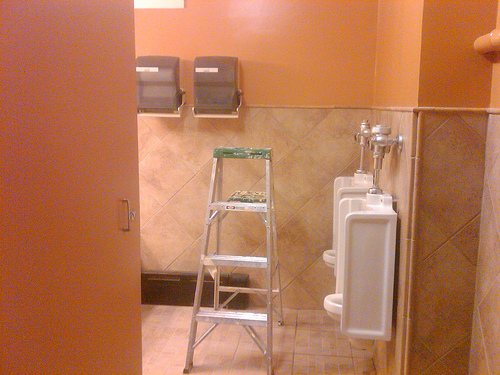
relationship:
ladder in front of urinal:
[183, 147, 284, 374] [323, 124, 404, 343]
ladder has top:
[183, 147, 284, 374] [214, 147, 273, 160]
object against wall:
[141, 269, 250, 311] [134, 0, 500, 375]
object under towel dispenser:
[141, 269, 250, 311] [192, 55, 242, 120]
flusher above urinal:
[354, 120, 372, 146] [322, 119, 378, 278]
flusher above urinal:
[369, 123, 397, 156] [323, 123, 404, 343]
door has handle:
[0, 0, 142, 374] [122, 199, 131, 232]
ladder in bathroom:
[183, 147, 284, 374] [0, 0, 499, 374]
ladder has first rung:
[183, 147, 284, 374] [195, 308, 268, 331]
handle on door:
[122, 199, 131, 232] [0, 0, 142, 374]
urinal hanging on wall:
[323, 124, 404, 343] [134, 0, 500, 375]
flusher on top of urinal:
[354, 120, 372, 146] [322, 119, 378, 278]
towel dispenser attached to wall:
[192, 55, 242, 120] [134, 0, 500, 375]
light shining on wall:
[228, 1, 285, 34] [134, 0, 500, 375]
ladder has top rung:
[183, 147, 284, 374] [209, 195, 268, 215]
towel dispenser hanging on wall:
[192, 55, 242, 120] [134, 0, 500, 375]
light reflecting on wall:
[228, 1, 285, 34] [134, 0, 500, 375]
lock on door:
[129, 209, 138, 221] [0, 0, 142, 374]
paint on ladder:
[233, 187, 268, 201] [183, 147, 284, 374]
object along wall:
[141, 269, 250, 311] [134, 0, 500, 375]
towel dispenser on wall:
[135, 55, 186, 119] [134, 0, 500, 375]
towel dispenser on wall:
[193, 55, 243, 118] [134, 0, 500, 375]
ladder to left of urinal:
[183, 147, 284, 374] [323, 124, 404, 343]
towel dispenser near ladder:
[193, 55, 243, 118] [183, 147, 284, 374]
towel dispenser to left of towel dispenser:
[135, 55, 186, 119] [193, 55, 243, 118]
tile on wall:
[134, 0, 500, 375] [155, 14, 344, 373]